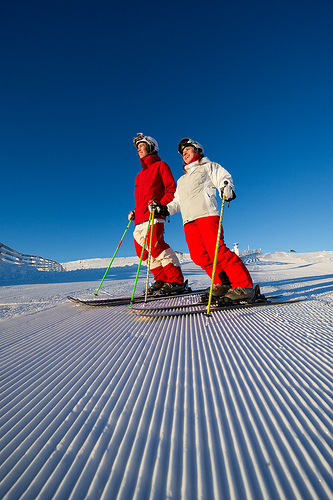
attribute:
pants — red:
[192, 220, 265, 307]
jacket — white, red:
[118, 156, 233, 231]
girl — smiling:
[168, 132, 210, 214]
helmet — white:
[118, 126, 212, 173]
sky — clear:
[168, 29, 283, 113]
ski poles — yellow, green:
[103, 202, 225, 339]